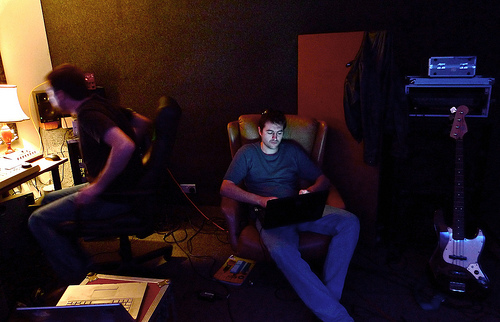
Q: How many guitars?
A: One.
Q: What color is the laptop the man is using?
A: Black.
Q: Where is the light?
A: On the desk.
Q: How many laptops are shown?
A: Two.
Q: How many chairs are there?
A: Two.